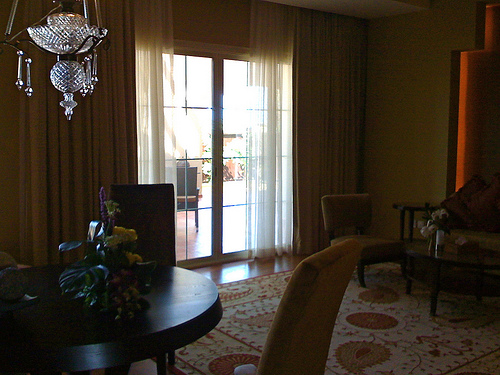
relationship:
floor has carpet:
[196, 253, 265, 296] [231, 278, 272, 352]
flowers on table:
[65, 181, 154, 330] [138, 276, 225, 363]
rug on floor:
[154, 259, 494, 375] [118, 251, 498, 375]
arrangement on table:
[54, 198, 153, 318] [2, 257, 224, 375]